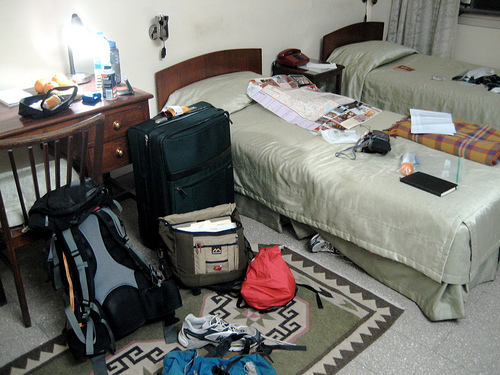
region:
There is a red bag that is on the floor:
[242, 242, 294, 316]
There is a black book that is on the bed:
[414, 156, 470, 196]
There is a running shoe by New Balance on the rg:
[190, 307, 256, 356]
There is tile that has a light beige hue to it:
[413, 338, 452, 366]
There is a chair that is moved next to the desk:
[13, 120, 103, 219]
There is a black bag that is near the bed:
[145, 109, 264, 246]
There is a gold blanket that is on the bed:
[418, 97, 499, 172]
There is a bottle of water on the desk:
[93, 32, 130, 97]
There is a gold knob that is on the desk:
[110, 120, 124, 142]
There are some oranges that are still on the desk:
[34, 73, 61, 93]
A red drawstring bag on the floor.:
[236, 244, 294, 310]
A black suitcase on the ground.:
[121, 98, 241, 249]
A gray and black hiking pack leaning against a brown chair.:
[23, 179, 183, 362]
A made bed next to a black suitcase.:
[155, 46, 499, 320]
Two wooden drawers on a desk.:
[76, 94, 154, 176]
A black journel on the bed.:
[400, 170, 460, 197]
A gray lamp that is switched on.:
[63, 14, 90, 84]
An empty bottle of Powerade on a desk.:
[100, 61, 118, 101]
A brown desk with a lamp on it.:
[0, 70, 154, 229]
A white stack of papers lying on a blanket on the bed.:
[408, 105, 458, 141]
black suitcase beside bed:
[136, 94, 240, 242]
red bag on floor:
[235, 235, 319, 325]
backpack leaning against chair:
[11, 173, 178, 357]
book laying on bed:
[401, 161, 467, 211]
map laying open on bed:
[238, 62, 397, 149]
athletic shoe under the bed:
[300, 223, 357, 267]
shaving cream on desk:
[91, 60, 128, 106]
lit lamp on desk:
[53, 6, 97, 88]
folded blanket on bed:
[393, 103, 499, 165]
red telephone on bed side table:
[275, 40, 314, 77]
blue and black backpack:
[18, 189, 188, 356]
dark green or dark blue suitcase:
[132, 121, 236, 208]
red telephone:
[276, 46, 313, 69]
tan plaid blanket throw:
[398, 111, 498, 163]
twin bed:
[154, 67, 494, 239]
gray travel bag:
[160, 211, 245, 283]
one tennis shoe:
[181, 314, 259, 351]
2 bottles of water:
[92, 36, 122, 74]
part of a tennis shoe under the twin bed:
[306, 233, 360, 266]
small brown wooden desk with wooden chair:
[1, 91, 151, 196]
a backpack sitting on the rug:
[22, 176, 189, 358]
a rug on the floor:
[5, 218, 410, 369]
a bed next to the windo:
[310, 10, 498, 135]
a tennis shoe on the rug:
[175, 306, 271, 351]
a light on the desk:
[51, 5, 97, 86]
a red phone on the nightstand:
[267, 35, 310, 67]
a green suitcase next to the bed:
[120, 101, 241, 251]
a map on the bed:
[236, 53, 384, 135]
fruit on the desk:
[20, 60, 80, 91]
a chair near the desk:
[0, 111, 113, 327]